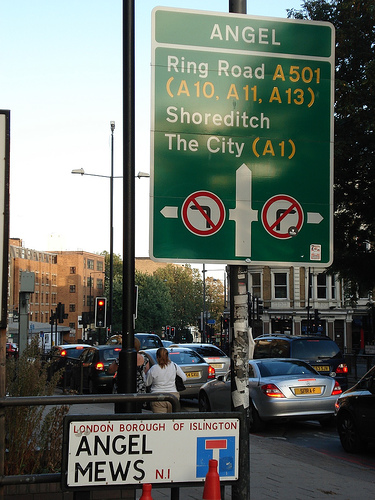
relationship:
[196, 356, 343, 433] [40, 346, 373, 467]
car on road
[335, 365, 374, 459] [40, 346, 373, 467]
car on road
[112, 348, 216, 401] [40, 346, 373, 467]
car on road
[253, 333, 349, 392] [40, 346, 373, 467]
car on road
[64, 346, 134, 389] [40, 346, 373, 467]
car on road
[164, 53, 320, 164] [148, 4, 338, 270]
label on sign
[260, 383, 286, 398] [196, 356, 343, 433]
light on car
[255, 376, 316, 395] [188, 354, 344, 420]
light on car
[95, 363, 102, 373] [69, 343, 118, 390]
light on car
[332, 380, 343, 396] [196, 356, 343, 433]
light on car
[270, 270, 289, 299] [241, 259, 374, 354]
window on building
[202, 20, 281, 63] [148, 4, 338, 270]
word on a sign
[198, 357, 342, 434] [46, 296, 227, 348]
car stopped at an intersection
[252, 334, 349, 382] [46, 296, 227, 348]
car stopped at an intersection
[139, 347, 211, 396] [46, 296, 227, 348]
car stopped at an intersection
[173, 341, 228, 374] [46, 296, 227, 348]
car stopped at an intersection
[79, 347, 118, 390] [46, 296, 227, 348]
car stopped at an intersection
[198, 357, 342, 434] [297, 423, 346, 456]
car on a street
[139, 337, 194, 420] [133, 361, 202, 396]
girl wearing a white shirt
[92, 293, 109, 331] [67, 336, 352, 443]
traffic light on street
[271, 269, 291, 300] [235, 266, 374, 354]
window on a building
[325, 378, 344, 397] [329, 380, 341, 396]
light on a car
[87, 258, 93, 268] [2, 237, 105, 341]
window of a building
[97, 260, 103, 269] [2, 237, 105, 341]
window of a building